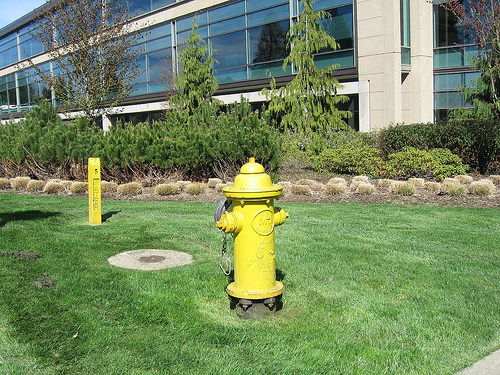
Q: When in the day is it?
A: Afternoon.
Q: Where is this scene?
A: Outside a building.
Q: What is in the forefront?
A: Fire hydrant.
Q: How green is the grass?
A: Very green.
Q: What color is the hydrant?
A: Yellow.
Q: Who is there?
A: No one.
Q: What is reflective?
A: Windows.